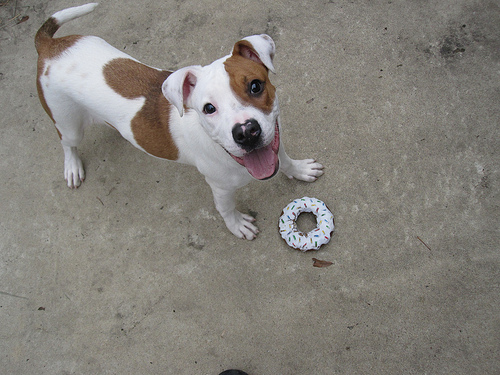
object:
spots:
[97, 58, 180, 166]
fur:
[53, 40, 87, 79]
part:
[95, 262, 229, 353]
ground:
[0, 0, 500, 372]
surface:
[128, 260, 271, 340]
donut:
[276, 193, 337, 254]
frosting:
[294, 198, 312, 210]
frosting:
[306, 232, 324, 244]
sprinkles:
[292, 234, 297, 240]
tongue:
[236, 145, 277, 182]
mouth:
[227, 116, 291, 183]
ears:
[156, 64, 198, 118]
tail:
[30, 6, 113, 52]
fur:
[97, 67, 149, 116]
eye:
[245, 78, 265, 99]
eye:
[201, 101, 220, 118]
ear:
[222, 27, 283, 77]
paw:
[220, 208, 262, 242]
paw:
[286, 156, 326, 184]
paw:
[61, 153, 86, 191]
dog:
[23, 1, 363, 241]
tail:
[28, 4, 103, 53]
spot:
[44, 63, 51, 79]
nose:
[230, 119, 262, 147]